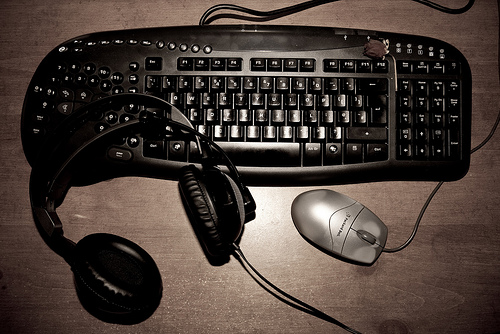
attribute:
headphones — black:
[21, 87, 259, 328]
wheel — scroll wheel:
[360, 233, 376, 243]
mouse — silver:
[290, 188, 386, 265]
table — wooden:
[413, 252, 494, 307]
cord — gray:
[386, 123, 498, 258]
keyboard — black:
[33, 15, 498, 235]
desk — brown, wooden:
[0, 0, 497, 331]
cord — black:
[230, 242, 360, 331]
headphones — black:
[158, 231, 372, 321]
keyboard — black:
[19, 22, 470, 186]